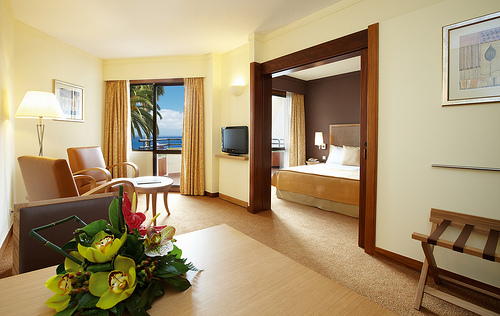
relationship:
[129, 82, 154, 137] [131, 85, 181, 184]
palm tree seen through window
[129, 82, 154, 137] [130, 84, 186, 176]
palm tree outside door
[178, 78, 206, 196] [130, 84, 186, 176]
curtains by door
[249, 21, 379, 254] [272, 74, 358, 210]
entranceway to bedroom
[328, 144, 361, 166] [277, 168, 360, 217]
pillows on bed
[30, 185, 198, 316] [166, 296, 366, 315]
plants on table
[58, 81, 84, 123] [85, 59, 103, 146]
painting on wall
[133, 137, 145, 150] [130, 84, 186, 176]
ocean outside door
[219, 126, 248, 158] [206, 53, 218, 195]
tv on wall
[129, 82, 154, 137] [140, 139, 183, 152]
palm tree behind balcony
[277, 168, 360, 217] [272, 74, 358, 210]
bed in bedroom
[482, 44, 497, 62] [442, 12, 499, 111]
leaf on picture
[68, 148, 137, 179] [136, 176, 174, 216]
chairs behind table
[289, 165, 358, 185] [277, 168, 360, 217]
cover on bed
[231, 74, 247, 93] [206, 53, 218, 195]
lamp on wall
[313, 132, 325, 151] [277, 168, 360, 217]
lamp next to bed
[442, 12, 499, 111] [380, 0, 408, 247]
picture on wall